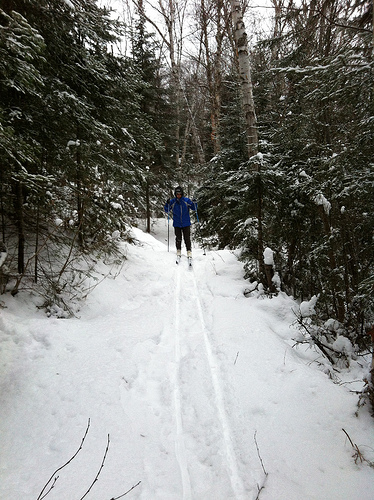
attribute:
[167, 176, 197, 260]
person — skiing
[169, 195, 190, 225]
jacket — blue, hooded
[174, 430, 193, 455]
snow — on, white, whitey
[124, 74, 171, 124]
trees — green, white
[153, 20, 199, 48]
sky — cloudy